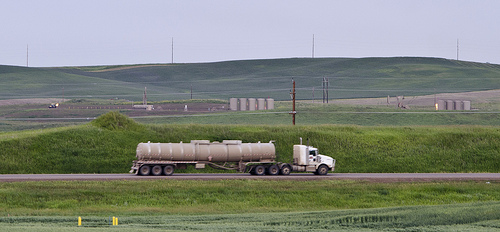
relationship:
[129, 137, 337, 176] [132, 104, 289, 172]
18 wheeler pulling tank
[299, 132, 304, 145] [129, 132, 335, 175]
pipe on truck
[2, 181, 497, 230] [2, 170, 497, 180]
grass on side of road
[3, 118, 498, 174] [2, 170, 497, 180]
grass on side of road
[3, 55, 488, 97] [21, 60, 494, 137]
hills in distance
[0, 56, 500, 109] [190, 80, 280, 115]
hills with pipes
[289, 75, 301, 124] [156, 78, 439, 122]
pole in field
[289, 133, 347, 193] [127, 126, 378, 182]
tractor of an truck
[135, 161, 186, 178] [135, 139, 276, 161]
wheels of a tank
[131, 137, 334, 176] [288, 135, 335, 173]
18 wheeler with cab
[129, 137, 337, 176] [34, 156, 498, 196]
18 wheeler driving down road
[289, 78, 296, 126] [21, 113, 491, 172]
pole in field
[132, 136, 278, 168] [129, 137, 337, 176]
tank on 18 wheeler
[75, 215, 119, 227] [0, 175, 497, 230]
markers in ground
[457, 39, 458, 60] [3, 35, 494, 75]
pole in distance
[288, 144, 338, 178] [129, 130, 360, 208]
cab of truck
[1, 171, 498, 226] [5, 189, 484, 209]
field of grass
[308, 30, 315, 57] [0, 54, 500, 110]
pole on hill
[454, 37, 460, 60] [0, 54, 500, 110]
pole on hill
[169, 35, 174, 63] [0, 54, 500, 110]
pole on hill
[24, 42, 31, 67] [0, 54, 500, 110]
pole on hill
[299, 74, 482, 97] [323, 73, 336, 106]
wires strung from poles